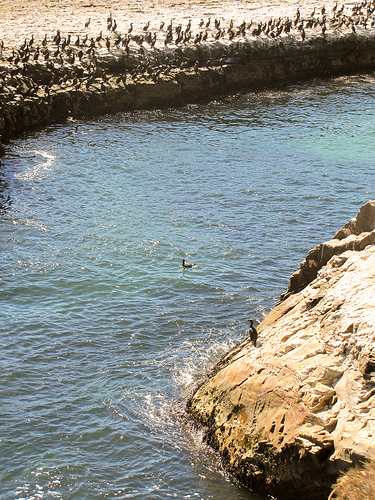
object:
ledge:
[1, 0, 375, 132]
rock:
[1, 0, 375, 120]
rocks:
[187, 200, 375, 500]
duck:
[208, 54, 226, 67]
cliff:
[0, 36, 375, 133]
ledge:
[189, 197, 375, 498]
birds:
[99, 81, 113, 93]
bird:
[84, 47, 93, 57]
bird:
[105, 12, 113, 22]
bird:
[80, 33, 89, 45]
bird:
[106, 18, 113, 31]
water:
[1, 72, 373, 498]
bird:
[84, 18, 91, 29]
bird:
[200, 17, 212, 30]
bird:
[142, 21, 151, 33]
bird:
[166, 18, 176, 33]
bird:
[125, 22, 134, 35]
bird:
[41, 33, 48, 47]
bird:
[151, 34, 157, 48]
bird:
[174, 33, 180, 47]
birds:
[193, 60, 199, 77]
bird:
[182, 254, 195, 267]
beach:
[0, 0, 375, 70]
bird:
[227, 19, 234, 33]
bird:
[179, 31, 184, 44]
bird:
[247, 319, 258, 347]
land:
[186, 205, 375, 500]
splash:
[173, 338, 245, 482]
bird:
[28, 34, 34, 49]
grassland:
[0, 2, 357, 44]